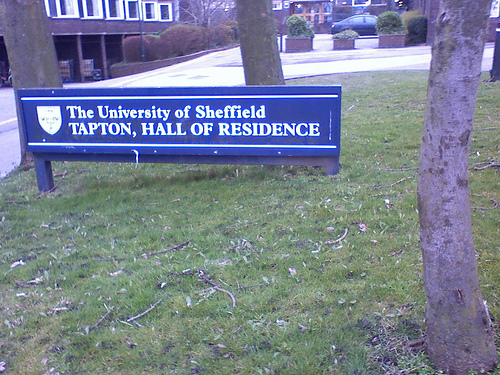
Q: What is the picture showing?
A: It is showing a lawn.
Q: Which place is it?
A: It is a lawn.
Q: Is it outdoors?
A: Yes, it is outdoors.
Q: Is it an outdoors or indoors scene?
A: It is outdoors.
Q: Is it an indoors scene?
A: No, it is outdoors.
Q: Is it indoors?
A: No, it is outdoors.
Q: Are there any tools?
A: No, there are no tools.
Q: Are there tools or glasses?
A: No, there are no tools or glasses.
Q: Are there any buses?
A: No, there are no buses.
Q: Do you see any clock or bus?
A: No, there are no buses or clocks.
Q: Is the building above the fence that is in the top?
A: Yes, the building is above the fence.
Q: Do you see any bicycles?
A: No, there are no bicycles.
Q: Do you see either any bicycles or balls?
A: No, there are no bicycles or balls.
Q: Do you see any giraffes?
A: No, there are no giraffes.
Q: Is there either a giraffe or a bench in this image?
A: No, there are no giraffes or benches.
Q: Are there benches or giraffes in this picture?
A: No, there are no giraffes or benches.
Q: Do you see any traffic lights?
A: No, there are no traffic lights.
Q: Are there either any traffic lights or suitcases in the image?
A: No, there are no traffic lights or suitcases.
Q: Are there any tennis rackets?
A: No, there are no tennis rackets.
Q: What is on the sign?
A: The logo is on the sign.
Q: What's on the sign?
A: The logo is on the sign.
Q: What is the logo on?
A: The logo is on the sign.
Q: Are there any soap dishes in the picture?
A: No, there are no soap dishes.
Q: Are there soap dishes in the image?
A: No, there are no soap dishes.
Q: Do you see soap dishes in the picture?
A: No, there are no soap dishes.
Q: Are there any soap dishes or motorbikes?
A: No, there are no soap dishes or motorbikes.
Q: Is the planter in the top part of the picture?
A: Yes, the planter is in the top of the image.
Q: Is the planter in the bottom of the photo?
A: No, the planter is in the top of the image.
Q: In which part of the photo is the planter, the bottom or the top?
A: The planter is in the top of the image.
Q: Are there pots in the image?
A: Yes, there is a pot.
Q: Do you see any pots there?
A: Yes, there is a pot.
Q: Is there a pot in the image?
A: Yes, there is a pot.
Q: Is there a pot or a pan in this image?
A: Yes, there is a pot.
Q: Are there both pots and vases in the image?
A: No, there is a pot but no vases.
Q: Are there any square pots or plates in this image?
A: Yes, there is a square pot.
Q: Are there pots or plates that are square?
A: Yes, the pot is square.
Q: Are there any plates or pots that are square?
A: Yes, the pot is square.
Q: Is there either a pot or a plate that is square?
A: Yes, the pot is square.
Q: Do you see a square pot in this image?
A: Yes, there is a square pot.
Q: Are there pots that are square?
A: Yes, there is a pot that is square.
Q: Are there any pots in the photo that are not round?
A: Yes, there is a square pot.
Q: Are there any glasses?
A: No, there are no glasses.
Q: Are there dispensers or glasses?
A: No, there are no glasses or dispensers.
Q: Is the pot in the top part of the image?
A: Yes, the pot is in the top of the image.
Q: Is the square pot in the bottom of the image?
A: No, the pot is in the top of the image.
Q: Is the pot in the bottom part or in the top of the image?
A: The pot is in the top of the image.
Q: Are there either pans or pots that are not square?
A: No, there is a pot but it is square.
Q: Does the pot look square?
A: Yes, the pot is square.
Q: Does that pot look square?
A: Yes, the pot is square.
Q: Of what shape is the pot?
A: The pot is square.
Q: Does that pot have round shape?
A: No, the pot is square.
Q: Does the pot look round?
A: No, the pot is square.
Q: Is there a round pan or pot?
A: No, there is a pot but it is square.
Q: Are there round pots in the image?
A: No, there is a pot but it is square.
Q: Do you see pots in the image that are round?
A: No, there is a pot but it is square.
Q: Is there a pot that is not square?
A: No, there is a pot but it is square.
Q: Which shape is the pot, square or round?
A: The pot is square.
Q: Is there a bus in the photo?
A: No, there are no buses.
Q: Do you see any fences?
A: Yes, there is a fence.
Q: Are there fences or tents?
A: Yes, there is a fence.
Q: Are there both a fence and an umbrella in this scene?
A: No, there is a fence but no umbrellas.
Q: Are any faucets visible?
A: No, there are no faucets.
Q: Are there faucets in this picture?
A: No, there are no faucets.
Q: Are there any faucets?
A: No, there are no faucets.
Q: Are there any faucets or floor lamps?
A: No, there are no faucets or floor lamps.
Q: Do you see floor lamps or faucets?
A: No, there are no faucets or floor lamps.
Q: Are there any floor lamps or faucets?
A: No, there are no faucets or floor lamps.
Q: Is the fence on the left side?
A: Yes, the fence is on the left of the image.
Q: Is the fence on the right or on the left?
A: The fence is on the left of the image.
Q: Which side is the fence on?
A: The fence is on the left of the image.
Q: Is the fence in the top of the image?
A: Yes, the fence is in the top of the image.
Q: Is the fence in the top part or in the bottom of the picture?
A: The fence is in the top of the image.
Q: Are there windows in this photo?
A: Yes, there is a window.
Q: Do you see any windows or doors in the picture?
A: Yes, there is a window.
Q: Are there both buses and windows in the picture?
A: No, there is a window but no buses.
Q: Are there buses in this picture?
A: No, there are no buses.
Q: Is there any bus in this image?
A: No, there are no buses.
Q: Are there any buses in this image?
A: No, there are no buses.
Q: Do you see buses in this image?
A: No, there are no buses.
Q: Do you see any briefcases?
A: No, there are no briefcases.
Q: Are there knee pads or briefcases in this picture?
A: No, there are no briefcases or knee pads.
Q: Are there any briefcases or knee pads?
A: No, there are no briefcases or knee pads.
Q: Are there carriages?
A: No, there are no carriages.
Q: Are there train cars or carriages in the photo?
A: No, there are no carriages or train cars.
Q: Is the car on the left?
A: No, the car is on the right of the image.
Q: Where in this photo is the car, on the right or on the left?
A: The car is on the right of the image.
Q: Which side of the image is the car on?
A: The car is on the right of the image.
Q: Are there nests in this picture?
A: No, there are no nests.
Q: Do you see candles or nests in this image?
A: No, there are no nests or candles.